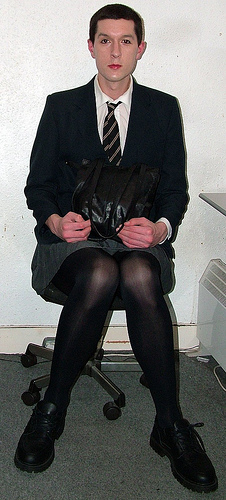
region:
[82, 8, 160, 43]
girl has short hair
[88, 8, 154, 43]
girl has brown hair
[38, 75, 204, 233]
girl has black jacket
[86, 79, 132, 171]
girl has white shirt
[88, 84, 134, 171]
black and tan tie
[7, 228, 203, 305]
girl has grey dress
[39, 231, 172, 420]
girl has black hose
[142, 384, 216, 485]
girl has black shoes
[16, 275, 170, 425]
girl on black chair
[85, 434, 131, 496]
floor is dark grey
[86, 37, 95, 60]
an ear of a person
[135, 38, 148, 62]
an ear of a person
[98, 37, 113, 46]
the eye of a person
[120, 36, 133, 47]
the eye of a person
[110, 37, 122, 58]
the nose of a person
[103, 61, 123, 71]
the mouth of a person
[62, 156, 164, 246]
a black purse on a lap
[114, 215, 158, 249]
the hand of a person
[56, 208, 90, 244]
the hand of a person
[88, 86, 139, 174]
a grey and black striped tie and a white dress shirt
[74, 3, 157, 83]
a woman with a very manly hair cut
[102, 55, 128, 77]
lips with red lipstick on them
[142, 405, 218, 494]
chunky black shoes with laces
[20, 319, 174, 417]
the legs of a rolling chair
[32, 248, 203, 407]
legs with black tights on them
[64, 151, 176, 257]
a black hand bag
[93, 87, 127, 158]
a black and gold tie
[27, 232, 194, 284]
short gray pin stripe skirt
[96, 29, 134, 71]
emotionless facial expression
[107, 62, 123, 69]
red lipstick on the man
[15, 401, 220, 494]
black dress shoes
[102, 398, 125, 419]
black wheel on the chair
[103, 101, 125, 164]
a black neck tie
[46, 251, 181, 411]
the man is wearing black tights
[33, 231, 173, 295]
the man is wearing a gray skirt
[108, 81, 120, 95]
Adam's apple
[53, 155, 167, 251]
the man is holding a purse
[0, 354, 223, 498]
gray carpet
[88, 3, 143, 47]
short brown hair